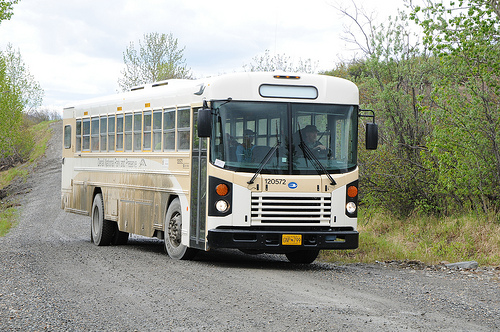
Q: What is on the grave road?
A: A white bus.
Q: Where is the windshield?
A: On the front of the bus.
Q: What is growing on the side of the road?
A: Trees.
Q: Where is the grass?
A: On the side of the road.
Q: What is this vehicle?
A: A bus.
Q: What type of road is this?
A: Dirt.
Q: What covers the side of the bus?
A: Mud.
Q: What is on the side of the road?
A: Trees.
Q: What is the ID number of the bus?
A: 120572.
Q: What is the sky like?
A: Partly cloudy.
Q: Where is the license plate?
A: The front of the bus.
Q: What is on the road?
A: Small rocks.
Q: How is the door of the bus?
A: Closed.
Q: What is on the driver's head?
A: A hat.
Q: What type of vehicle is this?
A: A bus.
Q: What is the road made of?
A: Gravel.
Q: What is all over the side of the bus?
A: Dirt.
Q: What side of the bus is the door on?
A: The right side.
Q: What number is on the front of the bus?
A: 120572.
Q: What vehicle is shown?
A: Bus.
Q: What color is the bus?
A: White.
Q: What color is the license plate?
A: Yellow.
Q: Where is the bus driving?
A: On a dirt road.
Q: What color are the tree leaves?
A: Green.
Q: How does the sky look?
A: Cloudy.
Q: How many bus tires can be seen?
A: Three.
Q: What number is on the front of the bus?
A: 120572.